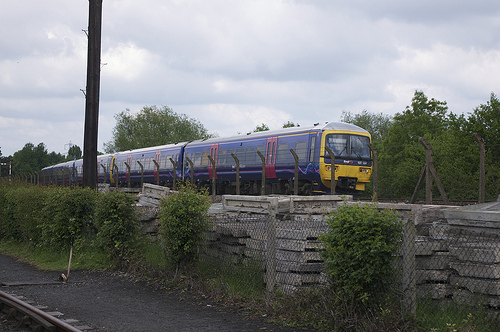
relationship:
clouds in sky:
[0, 0, 498, 158] [2, 1, 498, 158]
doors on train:
[152, 137, 277, 177] [98, 121, 381, 198]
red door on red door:
[264, 137, 276, 179] [264, 137, 276, 179]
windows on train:
[327, 122, 382, 164] [98, 121, 381, 198]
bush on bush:
[157, 181, 209, 277] [157, 181, 209, 277]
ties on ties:
[0, 286, 95, 330] [0, 287, 85, 332]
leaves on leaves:
[393, 89, 455, 149] [393, 89, 455, 149]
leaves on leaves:
[462, 90, 499, 167] [462, 90, 499, 167]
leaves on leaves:
[340, 108, 391, 148] [393, 89, 455, 149]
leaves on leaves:
[112, 106, 209, 151] [112, 106, 209, 151]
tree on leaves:
[59, 139, 92, 158] [67, 142, 82, 159]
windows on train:
[317, 122, 374, 192] [98, 121, 381, 198]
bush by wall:
[152, 174, 218, 286] [194, 182, 289, 299]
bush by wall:
[0, 173, 105, 260] [93, 181, 499, 326]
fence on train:
[5, 128, 494, 207] [98, 121, 381, 198]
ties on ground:
[0, 287, 85, 332] [2, 242, 316, 328]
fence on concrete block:
[94, 206, 496, 330] [273, 225, 306, 238]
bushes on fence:
[316, 203, 404, 308] [94, 206, 496, 330]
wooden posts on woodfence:
[229, 152, 244, 194] [40, 120, 376, 200]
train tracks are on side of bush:
[0, 174, 490, 205] [157, 181, 209, 277]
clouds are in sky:
[109, 0, 497, 85] [225, 32, 315, 97]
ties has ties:
[0, 287, 85, 332] [0, 287, 85, 332]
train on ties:
[98, 121, 381, 198] [0, 287, 85, 332]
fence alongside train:
[5, 128, 494, 207] [98, 121, 381, 198]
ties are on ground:
[0, 287, 85, 332] [2, 242, 316, 328]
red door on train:
[258, 134, 282, 175] [98, 121, 381, 198]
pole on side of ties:
[76, 3, 126, 225] [0, 287, 85, 332]